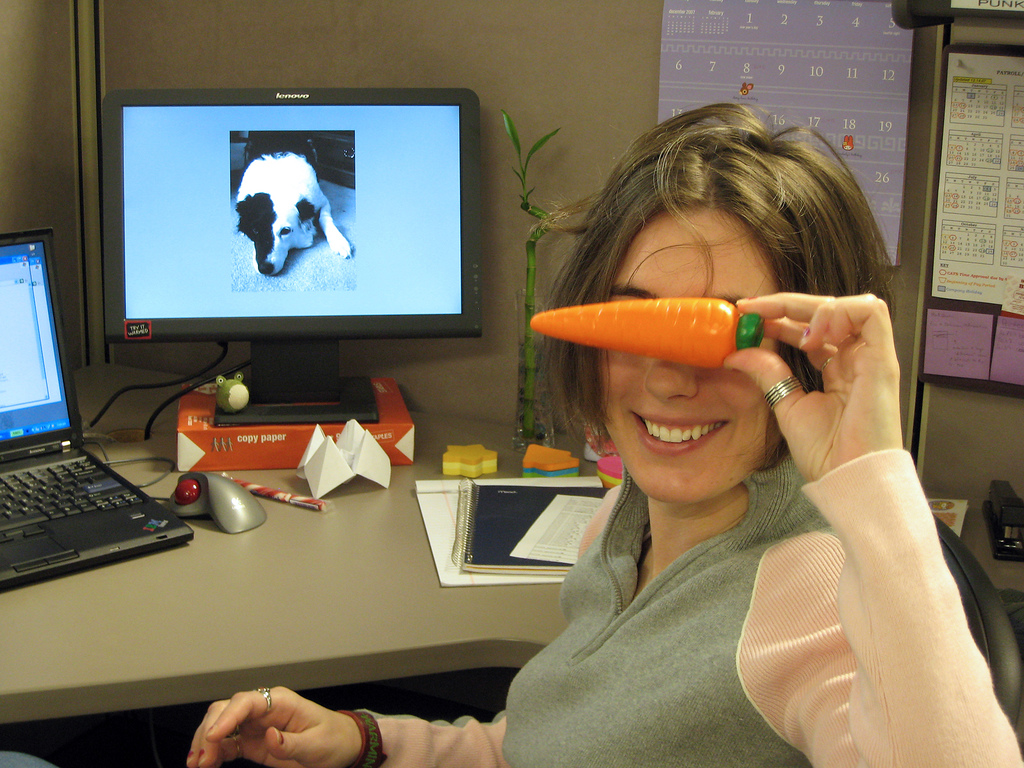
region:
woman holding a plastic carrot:
[1, 105, 1020, 766]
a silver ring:
[253, 682, 273, 722]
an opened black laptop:
[0, 232, 196, 590]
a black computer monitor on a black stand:
[102, 86, 482, 426]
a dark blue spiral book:
[449, 479, 609, 588]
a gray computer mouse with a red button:
[172, 473, 261, 534]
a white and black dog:
[235, 132, 354, 275]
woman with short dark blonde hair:
[1, 93, 1022, 764]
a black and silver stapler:
[983, 479, 1021, 559]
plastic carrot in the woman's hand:
[526, 290, 761, 361]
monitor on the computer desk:
[106, 88, 483, 427]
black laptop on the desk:
[1, 225, 198, 592]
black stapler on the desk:
[980, 478, 1022, 559]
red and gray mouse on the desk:
[162, 465, 264, 535]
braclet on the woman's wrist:
[333, 705, 385, 764]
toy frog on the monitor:
[206, 370, 252, 413]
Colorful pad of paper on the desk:
[443, 440, 497, 476]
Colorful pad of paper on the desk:
[522, 443, 580, 476]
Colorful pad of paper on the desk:
[596, 452, 626, 487]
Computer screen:
[121, 100, 466, 323]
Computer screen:
[0, 236, 73, 453]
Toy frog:
[213, 370, 248, 413]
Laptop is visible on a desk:
[0, 224, 191, 592]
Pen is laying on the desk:
[222, 474, 320, 510]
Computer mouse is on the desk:
[163, 465, 266, 536]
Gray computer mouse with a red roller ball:
[163, 463, 265, 533]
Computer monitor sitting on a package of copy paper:
[102, 83, 477, 475]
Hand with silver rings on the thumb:
[724, 292, 905, 473]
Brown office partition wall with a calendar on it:
[0, 4, 911, 362]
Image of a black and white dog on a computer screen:
[96, 94, 486, 338]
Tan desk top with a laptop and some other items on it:
[1, 232, 593, 723]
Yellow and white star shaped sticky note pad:
[437, 437, 502, 479]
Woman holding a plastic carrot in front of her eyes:
[163, 153, 1018, 767]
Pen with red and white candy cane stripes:
[229, 476, 327, 514]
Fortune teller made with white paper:
[286, 419, 392, 500]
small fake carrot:
[526, 286, 771, 379]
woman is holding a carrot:
[166, 93, 1014, 765]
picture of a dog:
[235, 152, 366, 283]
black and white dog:
[229, 149, 360, 279]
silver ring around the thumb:
[762, 370, 811, 409]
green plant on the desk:
[500, 120, 587, 430]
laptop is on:
[0, 224, 200, 623]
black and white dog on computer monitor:
[241, 130, 368, 280]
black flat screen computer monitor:
[107, 82, 482, 348]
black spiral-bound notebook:
[456, 481, 533, 568]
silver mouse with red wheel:
[173, 472, 263, 539]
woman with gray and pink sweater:
[552, 136, 968, 760]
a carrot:
[515, 293, 797, 369]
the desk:
[242, 566, 342, 634]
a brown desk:
[212, 535, 317, 638]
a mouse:
[180, 468, 272, 538]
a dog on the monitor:
[230, 164, 370, 286]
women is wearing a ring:
[256, 680, 276, 710]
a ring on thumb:
[770, 382, 799, 406]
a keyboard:
[19, 471, 71, 517]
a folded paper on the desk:
[290, 418, 399, 491]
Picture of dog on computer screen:
[226, 143, 362, 281]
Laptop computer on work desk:
[1, 221, 202, 596]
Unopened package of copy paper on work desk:
[169, 364, 423, 482]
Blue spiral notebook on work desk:
[440, 467, 611, 582]